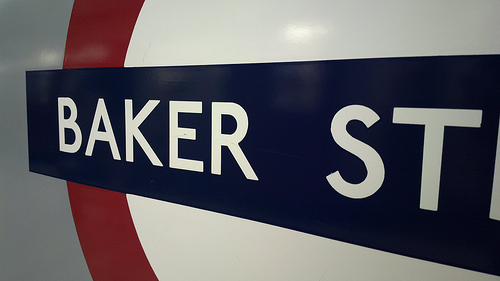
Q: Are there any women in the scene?
A: No, there are no women.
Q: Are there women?
A: No, there are no women.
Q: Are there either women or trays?
A: No, there are no women or trays.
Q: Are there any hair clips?
A: No, there are no hair clips.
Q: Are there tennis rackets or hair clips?
A: No, there are no hair clips or tennis rackets.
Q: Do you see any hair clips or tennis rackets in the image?
A: No, there are no hair clips or tennis rackets.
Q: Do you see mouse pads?
A: No, there are no mouse pads.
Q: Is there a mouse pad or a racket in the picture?
A: No, there are no mouse pads or rackets.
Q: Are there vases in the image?
A: No, there are no vases.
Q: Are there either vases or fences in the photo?
A: No, there are no vases or fences.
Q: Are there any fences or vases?
A: No, there are no vases or fences.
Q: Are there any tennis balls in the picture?
A: No, there are no tennis balls.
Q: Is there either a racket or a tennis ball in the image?
A: No, there are no tennis balls or rackets.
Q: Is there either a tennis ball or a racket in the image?
A: No, there are no tennis balls or rackets.